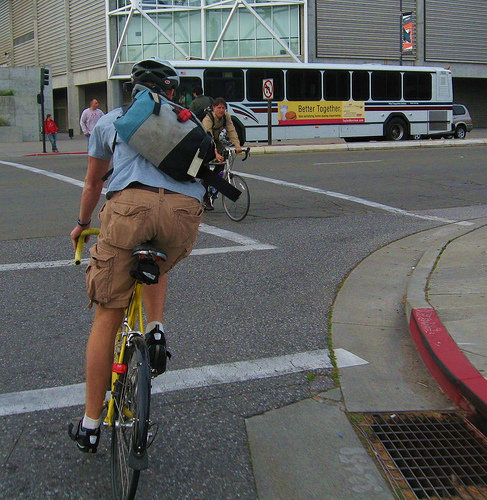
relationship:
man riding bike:
[61, 59, 213, 451] [69, 217, 178, 500]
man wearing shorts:
[61, 59, 213, 451] [83, 177, 204, 309]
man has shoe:
[61, 59, 213, 451] [64, 414, 102, 457]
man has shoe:
[61, 59, 213, 451] [137, 323, 173, 381]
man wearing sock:
[61, 59, 213, 451] [80, 413, 103, 432]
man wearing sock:
[61, 59, 213, 451] [145, 318, 168, 337]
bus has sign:
[154, 57, 456, 150] [273, 100, 368, 129]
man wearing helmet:
[61, 59, 213, 451] [129, 54, 182, 94]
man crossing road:
[61, 59, 213, 451] [1, 137, 487, 499]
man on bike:
[61, 59, 213, 451] [69, 217, 178, 500]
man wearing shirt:
[61, 59, 213, 451] [80, 102, 208, 206]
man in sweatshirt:
[79, 94, 111, 154] [77, 108, 105, 134]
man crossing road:
[79, 94, 111, 154] [1, 137, 487, 499]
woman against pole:
[43, 113, 64, 159] [37, 63, 49, 153]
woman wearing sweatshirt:
[43, 113, 64, 159] [43, 116, 57, 133]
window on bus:
[202, 65, 246, 107] [154, 57, 456, 150]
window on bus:
[244, 65, 287, 103] [154, 57, 456, 150]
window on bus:
[284, 64, 323, 104] [154, 57, 456, 150]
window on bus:
[320, 66, 350, 104] [154, 57, 456, 150]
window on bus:
[350, 68, 371, 103] [154, 57, 456, 150]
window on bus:
[368, 66, 402, 105] [154, 57, 456, 150]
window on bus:
[402, 68, 431, 102] [154, 57, 456, 150]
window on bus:
[174, 74, 204, 97] [154, 57, 456, 150]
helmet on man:
[129, 54, 182, 94] [61, 59, 213, 451]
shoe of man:
[64, 414, 102, 457] [61, 59, 213, 451]